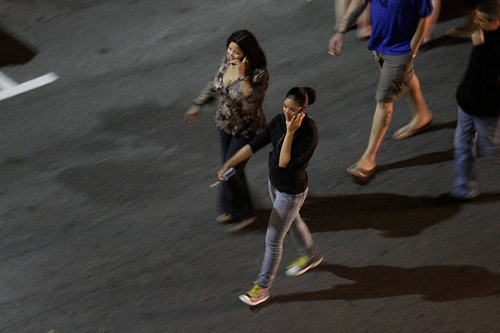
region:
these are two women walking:
[193, 30, 315, 306]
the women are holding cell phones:
[183, 25, 325, 316]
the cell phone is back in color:
[301, 107, 311, 114]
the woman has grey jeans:
[259, 192, 299, 227]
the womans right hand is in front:
[212, 140, 254, 187]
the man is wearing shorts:
[379, 61, 409, 95]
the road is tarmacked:
[3, 130, 180, 332]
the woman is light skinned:
[237, 150, 250, 157]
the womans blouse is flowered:
[212, 93, 242, 125]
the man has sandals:
[348, 162, 383, 177]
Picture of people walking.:
[161, 3, 485, 320]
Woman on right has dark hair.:
[264, 78, 326, 140]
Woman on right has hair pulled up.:
[275, 80, 320, 137]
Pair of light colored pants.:
[256, 180, 324, 287]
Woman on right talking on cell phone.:
[243, 82, 328, 199]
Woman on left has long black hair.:
[182, 24, 274, 230]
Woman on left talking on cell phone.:
[199, 30, 272, 109]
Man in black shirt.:
[453, 0, 495, 129]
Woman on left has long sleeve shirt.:
[195, 46, 272, 148]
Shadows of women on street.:
[320, 178, 492, 319]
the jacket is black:
[240, 117, 324, 204]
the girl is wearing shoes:
[225, 100, 343, 322]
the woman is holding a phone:
[260, 87, 306, 146]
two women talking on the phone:
[160, 23, 350, 225]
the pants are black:
[202, 117, 241, 227]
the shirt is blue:
[364, 0, 439, 86]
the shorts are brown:
[365, 27, 429, 118]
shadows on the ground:
[242, 144, 474, 324]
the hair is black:
[285, 85, 314, 106]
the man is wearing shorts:
[329, 12, 421, 182]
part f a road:
[22, 172, 164, 294]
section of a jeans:
[263, 212, 283, 246]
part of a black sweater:
[286, 163, 301, 177]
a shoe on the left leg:
[240, 290, 267, 307]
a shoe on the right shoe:
[292, 250, 316, 270]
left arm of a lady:
[274, 136, 290, 166]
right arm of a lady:
[223, 152, 250, 167]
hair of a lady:
[240, 33, 272, 60]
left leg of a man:
[365, 104, 395, 147]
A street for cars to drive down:
[3, 2, 490, 330]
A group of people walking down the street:
[188, 2, 499, 311]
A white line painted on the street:
[1, 68, 59, 100]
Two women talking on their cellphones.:
[192, 23, 329, 331]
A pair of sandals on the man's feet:
[335, 110, 437, 190]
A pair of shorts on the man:
[358, 40, 409, 108]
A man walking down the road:
[456, 7, 498, 199]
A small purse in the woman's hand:
[221, 160, 235, 181]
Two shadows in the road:
[247, 190, 493, 305]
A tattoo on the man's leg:
[379, 112, 392, 129]